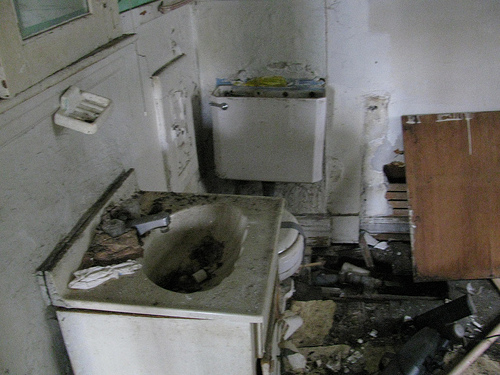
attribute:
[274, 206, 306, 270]
toilet — closed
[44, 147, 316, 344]
basin — dirty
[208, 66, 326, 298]
toilet — broken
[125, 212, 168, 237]
faucet — metal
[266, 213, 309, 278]
toilet — dirty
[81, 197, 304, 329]
sink — broken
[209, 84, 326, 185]
tank — white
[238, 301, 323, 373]
paint — curled, peeling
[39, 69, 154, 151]
soap holder — dirty, white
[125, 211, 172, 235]
faucet — silver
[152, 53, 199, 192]
wall panel — dirty, white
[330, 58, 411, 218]
drywall — ruined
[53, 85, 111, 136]
dish — dirty, soap